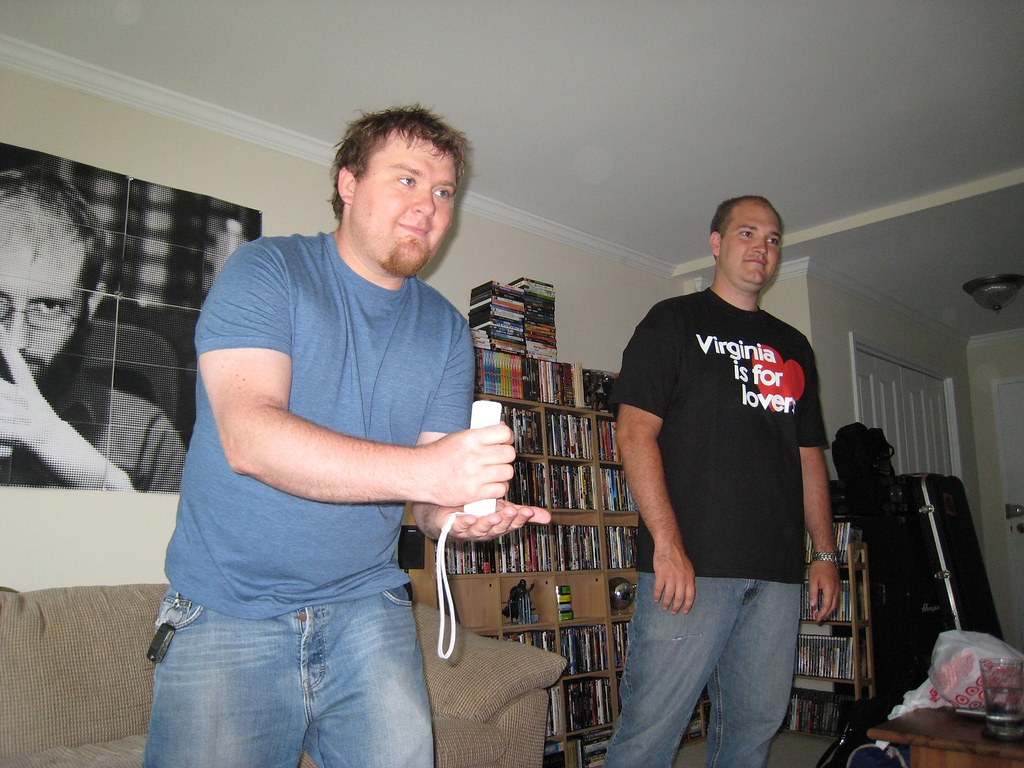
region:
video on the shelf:
[541, 521, 576, 579]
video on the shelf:
[561, 689, 585, 718]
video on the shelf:
[560, 651, 577, 680]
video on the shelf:
[623, 537, 639, 563]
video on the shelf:
[570, 375, 594, 404]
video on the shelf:
[492, 325, 537, 361]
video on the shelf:
[593, 474, 623, 506]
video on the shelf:
[497, 461, 555, 512]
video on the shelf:
[551, 376, 584, 416]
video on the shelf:
[554, 607, 605, 685]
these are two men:
[119, 104, 847, 659]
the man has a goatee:
[342, 124, 517, 299]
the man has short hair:
[289, 22, 561, 139]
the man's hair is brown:
[307, 72, 538, 168]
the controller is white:
[397, 367, 619, 580]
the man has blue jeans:
[172, 563, 382, 738]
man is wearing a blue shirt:
[126, 85, 561, 765]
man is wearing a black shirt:
[597, 192, 847, 766]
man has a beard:
[135, 104, 554, 766]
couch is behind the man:
[2, 102, 582, 766]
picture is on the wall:
[0, 83, 687, 581]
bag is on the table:
[862, 591, 1022, 765]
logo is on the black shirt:
[604, 288, 832, 592]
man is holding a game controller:
[126, 102, 564, 766]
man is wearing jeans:
[144, 94, 852, 766]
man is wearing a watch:
[593, 195, 859, 766]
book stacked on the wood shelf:
[469, 273, 523, 292]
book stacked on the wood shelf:
[509, 280, 557, 300]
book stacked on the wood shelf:
[519, 324, 555, 341]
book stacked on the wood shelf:
[482, 330, 524, 354]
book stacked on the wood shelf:
[536, 349, 546, 403]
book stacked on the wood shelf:
[551, 359, 564, 410]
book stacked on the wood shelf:
[564, 356, 583, 410]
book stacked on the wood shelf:
[598, 416, 609, 475]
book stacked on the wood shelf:
[468, 325, 527, 342]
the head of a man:
[298, 109, 486, 296]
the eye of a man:
[386, 162, 457, 213]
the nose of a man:
[412, 192, 439, 218]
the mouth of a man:
[390, 205, 448, 243]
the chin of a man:
[373, 241, 440, 287]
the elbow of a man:
[210, 437, 262, 495]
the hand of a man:
[425, 432, 523, 512]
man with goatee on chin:
[334, 108, 470, 277]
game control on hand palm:
[426, 396, 550, 543]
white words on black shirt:
[619, 289, 825, 585]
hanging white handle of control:
[434, 510, 473, 662]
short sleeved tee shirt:
[165, 231, 475, 612]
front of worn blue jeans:
[143, 591, 431, 765]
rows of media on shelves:
[459, 275, 628, 735]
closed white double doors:
[847, 329, 966, 479]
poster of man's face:
[0, 139, 260, 491]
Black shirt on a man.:
[612, 284, 821, 589]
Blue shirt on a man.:
[158, 225, 485, 621]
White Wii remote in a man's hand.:
[460, 402, 511, 524]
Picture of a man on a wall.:
[0, 156, 264, 517]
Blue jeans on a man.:
[138, 565, 456, 766]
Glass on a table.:
[967, 648, 1019, 728]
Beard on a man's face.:
[381, 224, 436, 288]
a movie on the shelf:
[557, 511, 611, 578]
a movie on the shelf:
[570, 632, 594, 680]